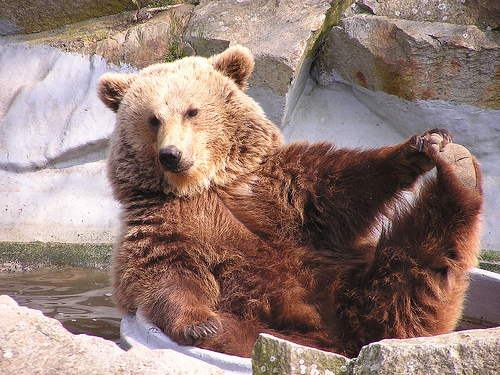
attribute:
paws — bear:
[167, 310, 232, 348]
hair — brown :
[93, 45, 486, 360]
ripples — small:
[60, 312, 120, 328]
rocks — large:
[314, 7, 374, 62]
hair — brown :
[304, 163, 351, 199]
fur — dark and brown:
[148, 221, 257, 296]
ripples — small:
[0, 267, 117, 340]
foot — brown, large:
[430, 145, 481, 194]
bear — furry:
[95, 67, 467, 327]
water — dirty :
[2, 263, 124, 338]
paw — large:
[426, 136, 486, 198]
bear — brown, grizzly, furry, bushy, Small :
[94, 38, 481, 357]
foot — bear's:
[426, 127, 491, 208]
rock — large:
[307, 1, 498, 155]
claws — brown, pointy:
[158, 310, 237, 362]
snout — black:
[158, 144, 183, 168]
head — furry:
[95, 44, 274, 197]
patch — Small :
[336, 283, 399, 307]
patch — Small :
[293, 269, 314, 286]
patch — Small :
[321, 256, 354, 285]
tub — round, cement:
[110, 238, 476, 372]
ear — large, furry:
[90, 70, 135, 111]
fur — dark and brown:
[157, 156, 397, 236]